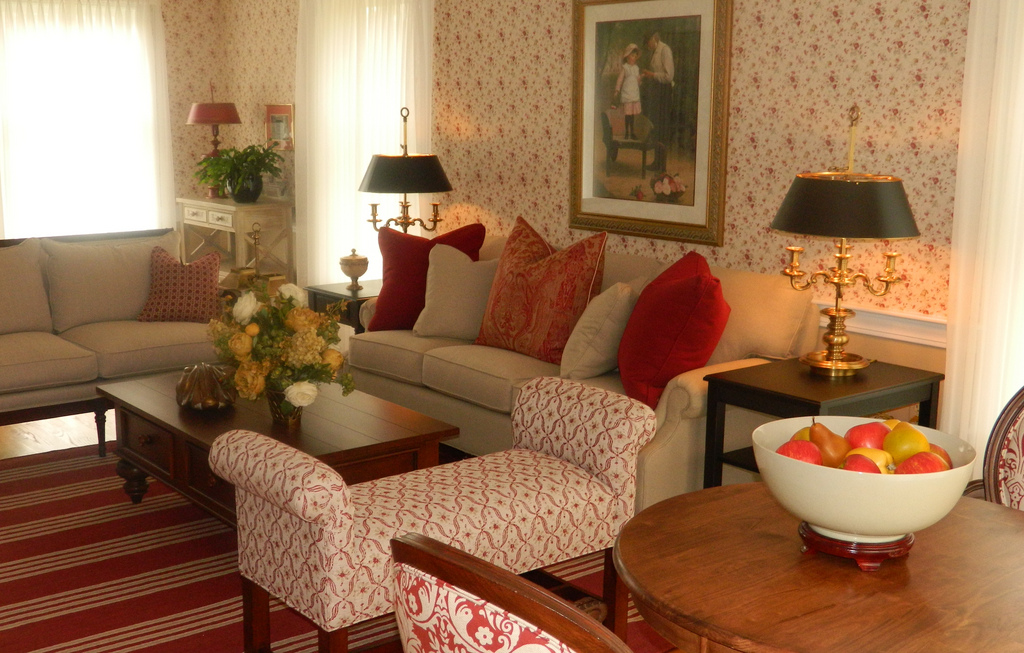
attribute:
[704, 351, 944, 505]
table — square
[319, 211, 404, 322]
table — small, white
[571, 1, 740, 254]
picture — framed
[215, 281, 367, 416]
bouquet — colorful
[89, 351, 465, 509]
table — shiny, wooden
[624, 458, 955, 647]
table — shiny, circular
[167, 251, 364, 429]
arrangement — floral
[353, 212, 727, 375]
pillows — red, beige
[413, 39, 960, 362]
wall — one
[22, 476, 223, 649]
rug — striped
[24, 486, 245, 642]
rug — white, red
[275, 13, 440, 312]
curtain — white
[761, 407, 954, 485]
fruit — some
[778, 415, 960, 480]
fruit — some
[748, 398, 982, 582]
bowl — wide, holding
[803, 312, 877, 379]
lamp holder — Gold plated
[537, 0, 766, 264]
wall painting — Gold framed